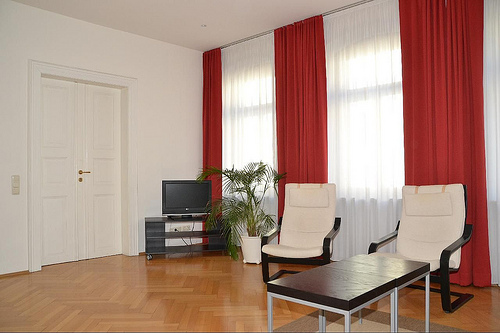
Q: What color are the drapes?
A: Red.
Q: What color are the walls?
A: White.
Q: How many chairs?
A: Two.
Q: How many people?
A: Zero.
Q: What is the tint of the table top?
A: Black.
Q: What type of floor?
A: Hard wood.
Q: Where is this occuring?
A: In the living room.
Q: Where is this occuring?
A: Living room.